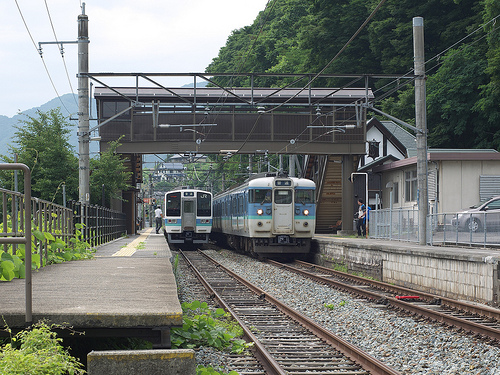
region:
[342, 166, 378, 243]
a curved white post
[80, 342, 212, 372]
piece of cement with faded yellow paint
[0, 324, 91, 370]
a light green plant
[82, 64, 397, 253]
bridge over train tracks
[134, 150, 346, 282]
blue and white train cars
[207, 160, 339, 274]
train with headlights on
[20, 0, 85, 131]
a few telephone wires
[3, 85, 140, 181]
a background of mountains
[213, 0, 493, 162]
some lush green foliage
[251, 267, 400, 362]
gravel between the train tracks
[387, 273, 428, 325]
red item on train track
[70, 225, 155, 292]
white stripe on sidewalk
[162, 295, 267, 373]
green shrub growing by rail road track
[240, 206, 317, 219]
two head lights on front of bus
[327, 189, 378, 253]
person standing on sidewalk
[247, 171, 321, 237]
blue and white train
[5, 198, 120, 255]
silver and gray rails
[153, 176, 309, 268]
two trains on tracks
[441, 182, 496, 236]
a parked silver car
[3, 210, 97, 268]
leaves growing thru bars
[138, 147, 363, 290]
a pair of trains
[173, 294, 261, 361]
a plant growing in the gravel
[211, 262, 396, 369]
a pair of train tracks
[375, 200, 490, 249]
a chain link fence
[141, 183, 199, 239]
a person boarding a train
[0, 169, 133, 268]
an old metal fence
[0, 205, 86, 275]
plants with broad leaves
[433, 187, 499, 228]
a small gold sedan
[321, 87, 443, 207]
a white building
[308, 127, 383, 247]
a old metal stairway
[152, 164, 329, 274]
Two trains on tracks.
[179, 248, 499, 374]
Railroad tracks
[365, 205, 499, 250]
A small chain-length fence.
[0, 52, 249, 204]
A view of the mountains in the back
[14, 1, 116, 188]
Power lines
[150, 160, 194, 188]
A white house in the back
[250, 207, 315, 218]
Lights on a train, which are on.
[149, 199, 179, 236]
A person boarding a train.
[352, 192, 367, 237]
A person waiting beside the fence.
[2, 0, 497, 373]
A train station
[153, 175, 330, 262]
two trains next to each other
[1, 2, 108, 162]
power lines in the sky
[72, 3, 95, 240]
electrical pole next to the train station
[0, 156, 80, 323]
brown metal railing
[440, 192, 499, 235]
silver car next to train station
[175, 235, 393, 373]
rusted metal railroad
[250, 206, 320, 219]
lit up headlights of a train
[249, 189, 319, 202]
front windows of a train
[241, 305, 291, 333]
wood between rails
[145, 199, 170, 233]
man walking to train